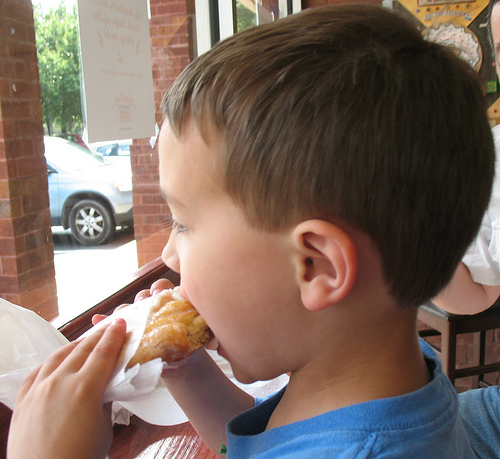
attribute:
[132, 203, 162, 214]
brick — red, small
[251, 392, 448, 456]
t-shirt — blue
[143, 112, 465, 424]
boy — little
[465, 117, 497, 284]
shirt — white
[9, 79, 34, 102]
brick — red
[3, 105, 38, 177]
red bricks — small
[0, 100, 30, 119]
brick — small, red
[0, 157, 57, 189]
bricks — red, small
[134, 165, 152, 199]
brick — red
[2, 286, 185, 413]
waxed paper — white 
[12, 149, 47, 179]
brick — red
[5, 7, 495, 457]
boy — little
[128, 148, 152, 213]
crabrick — red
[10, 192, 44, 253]
bricks — small, red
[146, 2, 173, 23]
brick — red